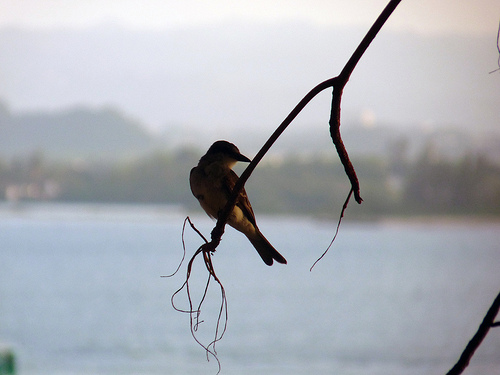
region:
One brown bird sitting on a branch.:
[182, 139, 311, 273]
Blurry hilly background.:
[20, 111, 182, 203]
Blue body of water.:
[13, 219, 164, 374]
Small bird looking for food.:
[181, 130, 311, 266]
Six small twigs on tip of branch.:
[165, 215, 245, 362]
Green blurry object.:
[0, 345, 22, 370]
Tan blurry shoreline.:
[367, 206, 484, 221]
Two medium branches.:
[175, 15, 495, 355]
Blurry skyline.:
[17, 7, 483, 104]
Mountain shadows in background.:
[11, 13, 498, 147]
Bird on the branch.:
[166, 106, 339, 287]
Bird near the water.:
[96, 107, 339, 358]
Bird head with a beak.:
[156, 95, 268, 176]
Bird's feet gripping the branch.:
[189, 205, 286, 287]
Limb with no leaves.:
[148, 100, 364, 370]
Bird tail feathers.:
[253, 212, 322, 319]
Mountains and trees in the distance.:
[76, 69, 325, 273]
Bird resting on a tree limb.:
[176, 111, 288, 286]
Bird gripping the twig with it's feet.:
[203, 210, 243, 290]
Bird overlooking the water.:
[163, 112, 312, 310]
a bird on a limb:
[123, 75, 392, 350]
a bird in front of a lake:
[0, 79, 482, 337]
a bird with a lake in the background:
[4, 87, 491, 357]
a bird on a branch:
[96, 67, 394, 353]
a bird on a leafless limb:
[80, 49, 372, 348]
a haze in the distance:
[14, 10, 485, 187]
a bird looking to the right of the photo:
[95, 70, 386, 327]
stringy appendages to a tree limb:
[131, 213, 231, 369]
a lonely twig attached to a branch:
[297, 167, 377, 297]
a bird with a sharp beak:
[115, 84, 404, 315]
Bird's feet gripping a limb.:
[168, 208, 258, 254]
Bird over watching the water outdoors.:
[185, 121, 333, 271]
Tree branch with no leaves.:
[205, 108, 421, 254]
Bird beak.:
[205, 110, 266, 165]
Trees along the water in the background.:
[95, 123, 350, 248]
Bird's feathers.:
[185, 145, 315, 257]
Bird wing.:
[210, 161, 261, 207]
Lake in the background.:
[57, 183, 198, 300]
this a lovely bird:
[46, 50, 383, 367]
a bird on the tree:
[161, 116, 493, 249]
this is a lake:
[82, 201, 243, 356]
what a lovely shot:
[7, 104, 414, 365]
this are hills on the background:
[26, 117, 136, 226]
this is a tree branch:
[266, 15, 408, 106]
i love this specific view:
[63, 129, 227, 336]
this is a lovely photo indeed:
[58, 90, 366, 365]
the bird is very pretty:
[183, 113, 388, 327]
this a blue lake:
[53, 183, 161, 347]